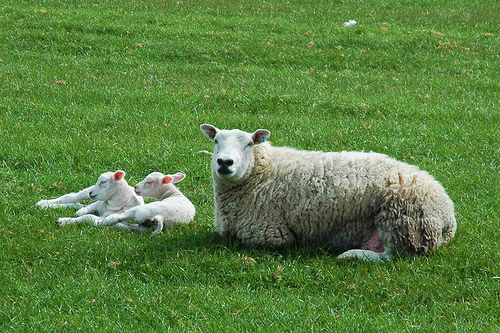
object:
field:
[1, 1, 484, 121]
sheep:
[199, 123, 458, 263]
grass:
[2, 1, 500, 332]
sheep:
[97, 171, 197, 236]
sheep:
[34, 169, 145, 228]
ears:
[171, 172, 186, 183]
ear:
[113, 169, 125, 183]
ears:
[200, 123, 220, 143]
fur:
[214, 145, 459, 249]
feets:
[60, 213, 103, 226]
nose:
[216, 157, 233, 167]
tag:
[261, 135, 266, 142]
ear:
[252, 128, 270, 145]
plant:
[343, 19, 357, 28]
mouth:
[217, 168, 234, 175]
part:
[2, 0, 76, 50]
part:
[282, 148, 321, 176]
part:
[79, 0, 154, 48]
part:
[327, 151, 368, 178]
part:
[375, 154, 416, 186]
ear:
[160, 174, 174, 185]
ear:
[171, 172, 186, 183]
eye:
[214, 138, 219, 144]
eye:
[247, 141, 253, 147]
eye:
[145, 181, 152, 185]